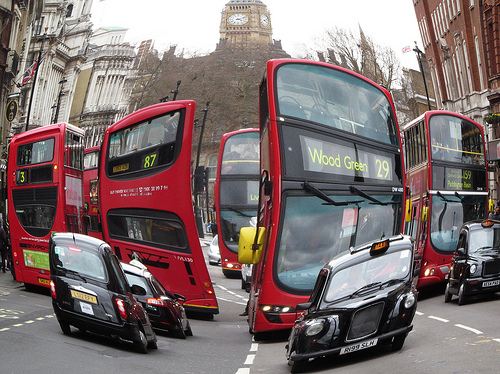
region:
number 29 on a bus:
[377, 159, 389, 176]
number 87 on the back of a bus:
[143, 154, 156, 166]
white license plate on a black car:
[338, 338, 377, 354]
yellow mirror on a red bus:
[236, 226, 264, 262]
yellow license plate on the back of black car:
[68, 288, 95, 301]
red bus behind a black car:
[247, 58, 407, 331]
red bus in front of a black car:
[96, 99, 218, 317]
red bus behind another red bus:
[216, 126, 261, 278]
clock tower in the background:
[218, 0, 272, 47]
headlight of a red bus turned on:
[260, 305, 294, 312]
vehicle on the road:
[291, 235, 432, 365]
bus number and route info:
[280, 121, 399, 181]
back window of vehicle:
[51, 245, 103, 272]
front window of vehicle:
[334, 260, 408, 283]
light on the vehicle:
[303, 320, 328, 337]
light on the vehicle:
[398, 293, 418, 312]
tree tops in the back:
[156, 35, 396, 126]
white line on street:
[224, 346, 263, 372]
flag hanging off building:
[19, 48, 61, 83]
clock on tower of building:
[226, 11, 252, 23]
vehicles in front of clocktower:
[7, 3, 482, 368]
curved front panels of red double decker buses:
[6, 55, 486, 335]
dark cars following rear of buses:
[40, 226, 190, 352]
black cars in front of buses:
[246, 51, 491, 361]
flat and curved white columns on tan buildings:
[5, 5, 135, 160]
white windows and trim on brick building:
[410, 0, 495, 135]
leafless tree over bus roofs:
[130, 30, 395, 130]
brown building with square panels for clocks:
[217, 0, 272, 41]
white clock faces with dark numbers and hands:
[221, 5, 266, 30]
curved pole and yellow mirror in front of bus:
[215, 120, 272, 280]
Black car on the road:
[286, 227, 426, 370]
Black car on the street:
[280, 226, 426, 372]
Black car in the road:
[281, 231, 423, 371]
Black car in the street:
[283, 230, 421, 372]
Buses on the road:
[2, 55, 498, 343]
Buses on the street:
[2, 54, 492, 340]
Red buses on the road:
[5, 52, 492, 339]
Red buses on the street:
[5, 50, 497, 342]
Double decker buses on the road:
[5, 51, 498, 350]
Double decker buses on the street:
[5, 54, 490, 340]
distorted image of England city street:
[7, 4, 498, 366]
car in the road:
[278, 233, 430, 365]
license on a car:
[337, 335, 389, 357]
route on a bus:
[302, 136, 397, 188]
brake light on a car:
[67, 240, 89, 255]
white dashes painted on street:
[232, 340, 261, 372]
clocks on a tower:
[223, 9, 275, 31]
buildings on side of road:
[405, 7, 493, 123]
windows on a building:
[451, 43, 473, 98]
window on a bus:
[276, 60, 395, 145]